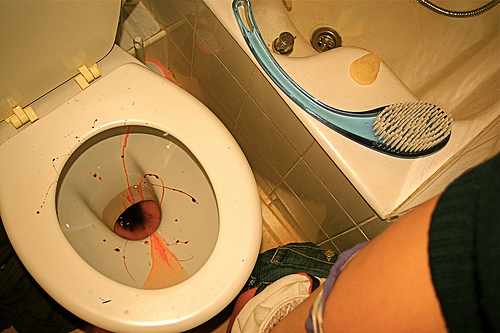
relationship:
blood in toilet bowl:
[93, 170, 95, 178] [24, 112, 224, 298]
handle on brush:
[233, 3, 373, 136] [238, 5, 459, 158]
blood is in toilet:
[114, 202, 148, 233] [0, 0, 261, 330]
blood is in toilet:
[80, 127, 198, 289] [0, 0, 261, 330]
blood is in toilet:
[109, 170, 199, 268] [0, 0, 261, 330]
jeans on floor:
[264, 254, 327, 278] [266, 195, 301, 252]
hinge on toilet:
[9, 97, 40, 139] [1, 40, 231, 312]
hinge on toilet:
[72, 52, 101, 88] [1, 40, 231, 312]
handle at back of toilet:
[130, 35, 153, 65] [0, 0, 261, 330]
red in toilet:
[88, 148, 182, 241] [0, 120, 265, 325]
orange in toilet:
[87, 124, 202, 290] [0, 52, 272, 326]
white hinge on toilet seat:
[74, 62, 106, 89] [113, 64, 189, 131]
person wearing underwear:
[270, 152, 497, 332] [303, 237, 371, 331]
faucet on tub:
[276, 14, 350, 61] [278, 7, 456, 121]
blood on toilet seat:
[35, 154, 60, 214] [0, 62, 264, 331]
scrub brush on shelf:
[233, 1, 453, 160] [204, 0, 497, 220]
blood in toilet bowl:
[80, 127, 198, 289] [1, 55, 264, 329]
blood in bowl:
[94, 147, 165, 271] [0, 46, 265, 324]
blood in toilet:
[117, 185, 169, 267] [0, 0, 261, 330]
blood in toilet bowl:
[94, 175, 165, 237] [52, 125, 222, 290]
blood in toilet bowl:
[105, 176, 146, 233] [1, 55, 264, 329]